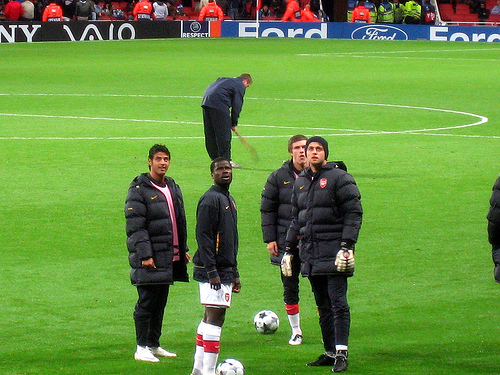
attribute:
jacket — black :
[123, 172, 193, 289]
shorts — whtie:
[199, 279, 236, 311]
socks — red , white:
[192, 316, 232, 369]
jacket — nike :
[280, 160, 370, 281]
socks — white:
[179, 331, 261, 369]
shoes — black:
[301, 332, 361, 372]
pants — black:
[309, 278, 351, 353]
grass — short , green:
[1, 40, 498, 373]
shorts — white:
[192, 270, 230, 307]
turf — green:
[10, 8, 498, 359]